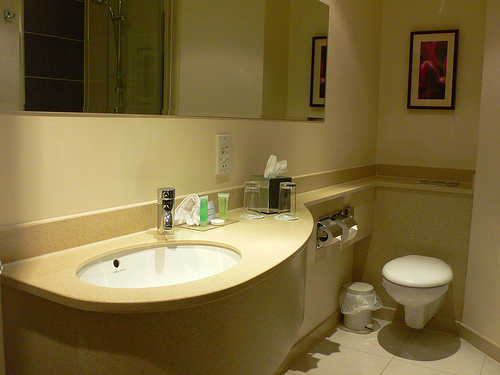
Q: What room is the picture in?
A: It is at the bathroom.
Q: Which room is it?
A: It is a bathroom.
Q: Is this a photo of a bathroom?
A: Yes, it is showing a bathroom.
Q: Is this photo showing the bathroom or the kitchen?
A: It is showing the bathroom.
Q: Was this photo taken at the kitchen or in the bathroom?
A: It was taken at the bathroom.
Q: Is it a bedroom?
A: No, it is a bathroom.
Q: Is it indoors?
A: Yes, it is indoors.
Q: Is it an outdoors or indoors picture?
A: It is indoors.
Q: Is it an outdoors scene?
A: No, it is indoors.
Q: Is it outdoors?
A: No, it is indoors.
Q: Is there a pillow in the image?
A: No, there are no pillows.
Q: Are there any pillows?
A: No, there are no pillows.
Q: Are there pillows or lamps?
A: No, there are no pillows or lamps.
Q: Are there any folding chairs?
A: No, there are no folding chairs.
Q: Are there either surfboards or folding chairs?
A: No, there are no folding chairs or surfboards.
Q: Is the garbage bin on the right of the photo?
A: Yes, the garbage bin is on the right of the image.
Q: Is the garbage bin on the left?
A: No, the garbage bin is on the right of the image.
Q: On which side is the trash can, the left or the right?
A: The trash can is on the right of the image.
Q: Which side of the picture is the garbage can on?
A: The garbage can is on the right of the image.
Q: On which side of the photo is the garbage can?
A: The garbage can is on the right of the image.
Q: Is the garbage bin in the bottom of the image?
A: Yes, the garbage bin is in the bottom of the image.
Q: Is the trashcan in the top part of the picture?
A: No, the trashcan is in the bottom of the image.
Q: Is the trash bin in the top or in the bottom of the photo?
A: The trash bin is in the bottom of the image.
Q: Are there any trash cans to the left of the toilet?
A: Yes, there is a trash can to the left of the toilet.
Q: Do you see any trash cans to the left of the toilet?
A: Yes, there is a trash can to the left of the toilet.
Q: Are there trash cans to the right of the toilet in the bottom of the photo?
A: No, the trash can is to the left of the toilet.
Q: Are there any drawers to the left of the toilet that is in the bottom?
A: No, there is a trash can to the left of the toilet.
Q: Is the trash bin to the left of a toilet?
A: Yes, the trash bin is to the left of a toilet.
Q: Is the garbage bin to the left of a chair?
A: No, the garbage bin is to the left of a toilet.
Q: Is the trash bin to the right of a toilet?
A: No, the trash bin is to the left of a toilet.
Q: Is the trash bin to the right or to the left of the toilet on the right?
A: The trash bin is to the left of the toilet.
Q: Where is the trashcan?
A: The trashcan is on the floor.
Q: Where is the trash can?
A: The trashcan is on the floor.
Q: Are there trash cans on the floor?
A: Yes, there is a trash can on the floor.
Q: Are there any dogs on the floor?
A: No, there is a trash can on the floor.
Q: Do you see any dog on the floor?
A: No, there is a trash can on the floor.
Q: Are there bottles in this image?
A: Yes, there is a bottle.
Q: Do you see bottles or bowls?
A: Yes, there is a bottle.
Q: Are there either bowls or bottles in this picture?
A: Yes, there is a bottle.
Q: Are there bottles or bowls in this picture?
A: Yes, there is a bottle.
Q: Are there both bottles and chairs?
A: No, there is a bottle but no chairs.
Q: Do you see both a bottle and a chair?
A: No, there is a bottle but no chairs.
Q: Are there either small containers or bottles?
A: Yes, there is a small bottle.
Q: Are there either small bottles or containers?
A: Yes, there is a small bottle.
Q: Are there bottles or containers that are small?
A: Yes, the bottle is small.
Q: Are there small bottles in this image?
A: Yes, there is a small bottle.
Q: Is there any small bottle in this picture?
A: Yes, there is a small bottle.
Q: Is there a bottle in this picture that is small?
A: Yes, there is a bottle that is small.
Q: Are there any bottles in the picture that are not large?
A: Yes, there is a small bottle.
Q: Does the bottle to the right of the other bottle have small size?
A: Yes, the bottle is small.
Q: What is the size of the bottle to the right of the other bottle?
A: The bottle is small.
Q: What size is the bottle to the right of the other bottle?
A: The bottle is small.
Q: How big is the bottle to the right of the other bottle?
A: The bottle is small.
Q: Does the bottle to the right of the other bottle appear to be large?
A: No, the bottle is small.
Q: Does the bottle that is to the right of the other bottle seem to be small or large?
A: The bottle is small.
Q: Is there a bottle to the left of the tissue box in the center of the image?
A: Yes, there is a bottle to the left of the tissue box.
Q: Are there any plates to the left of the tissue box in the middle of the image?
A: No, there is a bottle to the left of the tissue box.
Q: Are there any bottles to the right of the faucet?
A: Yes, there is a bottle to the right of the faucet.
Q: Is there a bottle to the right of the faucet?
A: Yes, there is a bottle to the right of the faucet.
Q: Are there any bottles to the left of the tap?
A: No, the bottle is to the right of the tap.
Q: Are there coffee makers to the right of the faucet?
A: No, there is a bottle to the right of the faucet.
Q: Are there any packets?
A: No, there are no packets.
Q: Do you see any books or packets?
A: No, there are no packets or books.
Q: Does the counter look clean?
A: Yes, the counter is clean.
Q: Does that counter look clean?
A: Yes, the counter is clean.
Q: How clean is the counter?
A: The counter is clean.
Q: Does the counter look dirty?
A: No, the counter is clean.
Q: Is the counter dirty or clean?
A: The counter is clean.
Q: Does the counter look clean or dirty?
A: The counter is clean.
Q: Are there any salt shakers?
A: No, there are no salt shakers.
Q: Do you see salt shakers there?
A: No, there are no salt shakers.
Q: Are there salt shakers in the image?
A: No, there are no salt shakers.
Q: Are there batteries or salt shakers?
A: No, there are no salt shakers or batteries.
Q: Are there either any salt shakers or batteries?
A: No, there are no salt shakers or batteries.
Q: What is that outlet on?
A: The outlet is on the wall.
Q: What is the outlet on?
A: The outlet is on the wall.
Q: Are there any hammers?
A: No, there are no hammers.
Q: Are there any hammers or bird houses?
A: No, there are no hammers or bird houses.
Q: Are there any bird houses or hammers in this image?
A: No, there are no hammers or bird houses.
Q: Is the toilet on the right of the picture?
A: Yes, the toilet is on the right of the image.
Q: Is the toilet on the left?
A: No, the toilet is on the right of the image.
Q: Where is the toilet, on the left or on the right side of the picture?
A: The toilet is on the right of the image.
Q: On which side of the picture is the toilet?
A: The toilet is on the right of the image.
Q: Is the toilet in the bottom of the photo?
A: Yes, the toilet is in the bottom of the image.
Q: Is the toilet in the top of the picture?
A: No, the toilet is in the bottom of the image.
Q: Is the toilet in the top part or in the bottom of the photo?
A: The toilet is in the bottom of the image.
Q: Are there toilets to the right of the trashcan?
A: Yes, there is a toilet to the right of the trashcan.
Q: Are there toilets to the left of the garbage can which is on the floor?
A: No, the toilet is to the right of the trash can.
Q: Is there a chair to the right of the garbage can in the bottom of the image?
A: No, there is a toilet to the right of the trash bin.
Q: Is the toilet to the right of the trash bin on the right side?
A: Yes, the toilet is to the right of the trash bin.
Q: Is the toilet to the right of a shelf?
A: No, the toilet is to the right of the trash bin.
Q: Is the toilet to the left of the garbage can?
A: No, the toilet is to the right of the garbage can.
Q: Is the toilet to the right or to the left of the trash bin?
A: The toilet is to the right of the trash bin.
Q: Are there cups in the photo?
A: Yes, there is a cup.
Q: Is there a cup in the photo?
A: Yes, there is a cup.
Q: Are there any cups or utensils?
A: Yes, there is a cup.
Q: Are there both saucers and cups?
A: No, there is a cup but no saucers.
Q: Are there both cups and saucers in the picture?
A: No, there is a cup but no saucers.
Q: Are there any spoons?
A: No, there are no spoons.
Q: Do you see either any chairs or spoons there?
A: No, there are no spoons or chairs.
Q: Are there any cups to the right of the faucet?
A: Yes, there is a cup to the right of the faucet.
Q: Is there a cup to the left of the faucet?
A: No, the cup is to the right of the faucet.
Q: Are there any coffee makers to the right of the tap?
A: No, there is a cup to the right of the tap.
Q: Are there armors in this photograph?
A: No, there are no armors.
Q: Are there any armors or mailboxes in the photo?
A: No, there are no armors or mailboxes.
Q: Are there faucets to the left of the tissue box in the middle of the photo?
A: Yes, there is a faucet to the left of the tissue box.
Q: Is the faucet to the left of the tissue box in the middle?
A: Yes, the faucet is to the left of the tissue box.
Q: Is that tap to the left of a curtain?
A: No, the tap is to the left of the tissue box.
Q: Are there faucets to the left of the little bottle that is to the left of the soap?
A: Yes, there is a faucet to the left of the bottle.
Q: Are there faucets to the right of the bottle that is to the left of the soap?
A: No, the faucet is to the left of the bottle.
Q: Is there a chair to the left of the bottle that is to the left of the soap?
A: No, there is a faucet to the left of the bottle.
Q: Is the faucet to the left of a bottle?
A: Yes, the faucet is to the left of a bottle.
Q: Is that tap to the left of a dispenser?
A: No, the tap is to the left of a bottle.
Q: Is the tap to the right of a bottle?
A: No, the tap is to the left of a bottle.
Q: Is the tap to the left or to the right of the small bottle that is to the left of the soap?
A: The tap is to the left of the bottle.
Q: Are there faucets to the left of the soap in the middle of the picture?
A: Yes, there is a faucet to the left of the soap.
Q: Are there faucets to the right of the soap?
A: No, the faucet is to the left of the soap.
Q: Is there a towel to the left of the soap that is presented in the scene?
A: No, there is a faucet to the left of the soap.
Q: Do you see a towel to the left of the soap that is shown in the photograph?
A: No, there is a faucet to the left of the soap.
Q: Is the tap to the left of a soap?
A: Yes, the tap is to the left of a soap.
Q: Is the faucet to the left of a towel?
A: No, the faucet is to the left of a soap.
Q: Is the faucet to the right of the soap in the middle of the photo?
A: No, the faucet is to the left of the soap.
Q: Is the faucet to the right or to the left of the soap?
A: The faucet is to the left of the soap.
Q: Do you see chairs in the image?
A: No, there are no chairs.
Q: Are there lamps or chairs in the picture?
A: No, there are no chairs or lamps.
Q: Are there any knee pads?
A: No, there are no knee pads.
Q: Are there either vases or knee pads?
A: No, there are no knee pads or vases.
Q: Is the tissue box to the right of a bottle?
A: Yes, the tissue box is to the right of a bottle.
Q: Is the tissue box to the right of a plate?
A: No, the tissue box is to the right of a bottle.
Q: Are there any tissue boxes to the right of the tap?
A: Yes, there is a tissue box to the right of the tap.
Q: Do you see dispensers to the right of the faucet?
A: No, there is a tissue box to the right of the faucet.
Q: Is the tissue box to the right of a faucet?
A: Yes, the tissue box is to the right of a faucet.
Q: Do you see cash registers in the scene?
A: No, there are no cash registers.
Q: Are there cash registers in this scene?
A: No, there are no cash registers.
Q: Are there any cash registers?
A: No, there are no cash registers.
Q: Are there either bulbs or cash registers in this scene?
A: No, there are no cash registers or bulbs.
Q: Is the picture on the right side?
A: Yes, the picture is on the right of the image.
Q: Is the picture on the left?
A: No, the picture is on the right of the image.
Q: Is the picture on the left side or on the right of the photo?
A: The picture is on the right of the image.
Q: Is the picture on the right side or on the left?
A: The picture is on the right of the image.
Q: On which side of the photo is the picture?
A: The picture is on the right of the image.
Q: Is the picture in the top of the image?
A: Yes, the picture is in the top of the image.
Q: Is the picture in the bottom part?
A: No, the picture is in the top of the image.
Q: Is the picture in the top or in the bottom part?
A: The picture is in the top of the image.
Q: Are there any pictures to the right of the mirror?
A: Yes, there is a picture to the right of the mirror.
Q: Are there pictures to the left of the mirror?
A: No, the picture is to the right of the mirror.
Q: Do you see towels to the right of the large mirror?
A: No, there is a picture to the right of the mirror.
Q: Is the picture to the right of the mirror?
A: Yes, the picture is to the right of the mirror.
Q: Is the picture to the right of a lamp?
A: No, the picture is to the right of the mirror.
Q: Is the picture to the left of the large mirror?
A: No, the picture is to the right of the mirror.